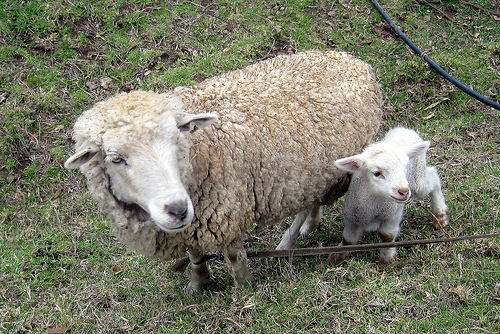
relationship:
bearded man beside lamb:
[63, 49, 382, 295] [348, 129, 452, 251]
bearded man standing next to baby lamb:
[63, 49, 382, 295] [326, 126, 448, 264]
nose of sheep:
[161, 197, 194, 232] [61, 80, 286, 299]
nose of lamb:
[394, 188, 411, 198] [326, 121, 457, 261]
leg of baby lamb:
[374, 224, 405, 267] [326, 126, 448, 264]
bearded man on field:
[63, 49, 382, 295] [3, 4, 497, 331]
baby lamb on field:
[326, 126, 448, 264] [3, 4, 497, 331]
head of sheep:
[64, 93, 214, 244] [328, 123, 460, 275]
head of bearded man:
[334, 141, 430, 204] [63, 49, 382, 295]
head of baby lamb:
[359, 142, 414, 200] [326, 126, 448, 264]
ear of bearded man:
[175, 107, 217, 132] [63, 49, 382, 295]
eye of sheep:
[103, 151, 138, 176] [50, 34, 392, 299]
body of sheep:
[186, 51, 379, 231] [59, 48, 471, 286]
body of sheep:
[336, 122, 433, 257] [67, 57, 374, 267]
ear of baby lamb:
[335, 150, 362, 177] [326, 126, 448, 264]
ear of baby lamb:
[408, 136, 430, 157] [326, 126, 448, 264]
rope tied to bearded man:
[169, 232, 499, 273] [63, 49, 382, 295]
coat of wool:
[204, 55, 338, 177] [334, 100, 381, 135]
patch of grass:
[50, 255, 151, 315] [29, 248, 194, 332]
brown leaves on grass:
[415, 5, 487, 45] [1, 5, 498, 332]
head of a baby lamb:
[334, 141, 430, 204] [326, 126, 448, 264]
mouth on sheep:
[154, 215, 196, 233] [50, 34, 392, 299]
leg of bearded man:
[226, 250, 252, 303] [63, 49, 382, 295]